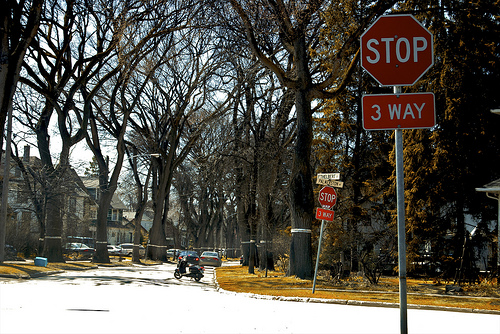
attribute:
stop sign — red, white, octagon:
[358, 14, 437, 88]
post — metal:
[391, 88, 408, 333]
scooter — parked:
[177, 256, 200, 283]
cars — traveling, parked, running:
[177, 242, 225, 266]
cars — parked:
[60, 244, 183, 259]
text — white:
[364, 34, 427, 66]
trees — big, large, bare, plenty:
[5, 3, 316, 280]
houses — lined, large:
[3, 145, 176, 250]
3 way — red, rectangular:
[367, 98, 434, 124]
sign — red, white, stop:
[359, 91, 440, 135]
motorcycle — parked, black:
[173, 254, 207, 282]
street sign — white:
[318, 167, 345, 188]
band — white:
[287, 222, 308, 237]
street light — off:
[92, 146, 166, 261]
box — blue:
[32, 255, 52, 267]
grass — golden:
[10, 252, 73, 276]